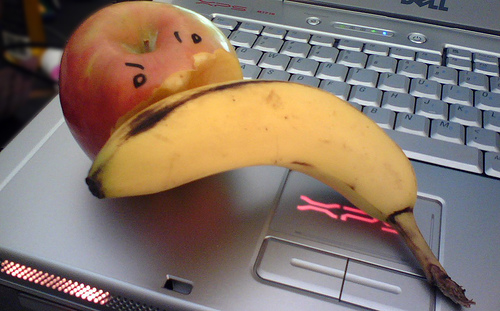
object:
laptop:
[0, 0, 500, 310]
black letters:
[255, 50, 291, 68]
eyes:
[185, 29, 202, 44]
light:
[379, 29, 388, 36]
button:
[406, 30, 430, 43]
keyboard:
[195, 11, 498, 180]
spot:
[228, 96, 242, 105]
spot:
[259, 126, 274, 134]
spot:
[280, 113, 288, 123]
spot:
[325, 108, 337, 117]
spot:
[289, 157, 314, 169]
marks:
[124, 31, 206, 89]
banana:
[83, 79, 478, 308]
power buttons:
[304, 14, 324, 26]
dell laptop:
[399, 0, 448, 12]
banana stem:
[386, 206, 478, 307]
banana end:
[83, 169, 111, 199]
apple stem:
[140, 37, 154, 51]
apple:
[58, 0, 244, 163]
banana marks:
[124, 78, 303, 139]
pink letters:
[295, 192, 345, 223]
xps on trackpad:
[296, 190, 411, 234]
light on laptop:
[369, 25, 379, 33]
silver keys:
[207, 12, 497, 181]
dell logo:
[397, 0, 452, 14]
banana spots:
[261, 90, 286, 109]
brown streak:
[122, 77, 292, 143]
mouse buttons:
[339, 256, 437, 310]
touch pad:
[252, 164, 450, 309]